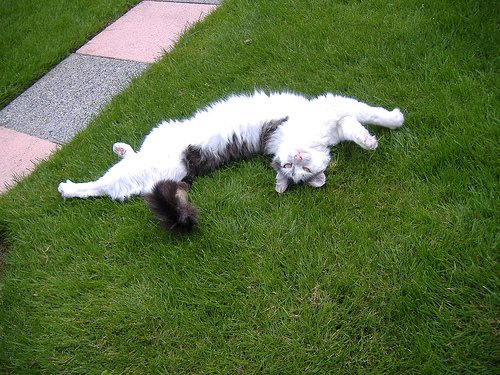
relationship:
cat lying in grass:
[56, 87, 404, 234] [2, 4, 498, 369]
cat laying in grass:
[50, 80, 411, 238] [48, 62, 497, 262]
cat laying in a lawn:
[50, 80, 411, 238] [10, 7, 499, 356]